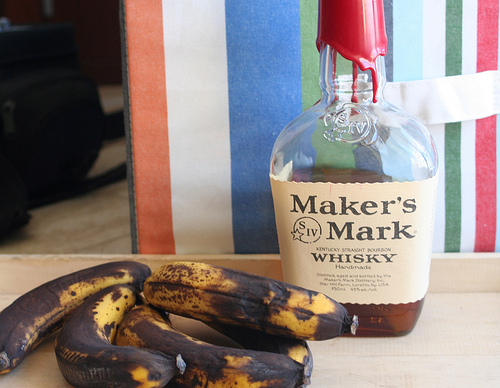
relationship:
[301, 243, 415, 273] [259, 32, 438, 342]
word on bottle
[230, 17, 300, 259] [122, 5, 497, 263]
stripe on wall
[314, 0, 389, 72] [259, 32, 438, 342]
top on bottle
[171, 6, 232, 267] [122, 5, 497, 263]
stripe on wall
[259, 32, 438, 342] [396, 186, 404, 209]
bottle has apostrophe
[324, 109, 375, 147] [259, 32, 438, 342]
circle on bottle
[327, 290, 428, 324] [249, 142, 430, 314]
liquid in glass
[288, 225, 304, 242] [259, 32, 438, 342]
star on bottle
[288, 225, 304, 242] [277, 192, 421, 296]
star on label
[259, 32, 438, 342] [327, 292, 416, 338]
bottle has whisky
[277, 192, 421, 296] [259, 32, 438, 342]
label on bottle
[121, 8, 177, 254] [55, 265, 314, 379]
stripe behind bananas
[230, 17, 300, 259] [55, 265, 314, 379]
stripe behind bananas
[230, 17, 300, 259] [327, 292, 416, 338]
stripe behind whisky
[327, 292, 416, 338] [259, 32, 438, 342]
whisky in bottle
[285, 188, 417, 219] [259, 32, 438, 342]
maker's on bottle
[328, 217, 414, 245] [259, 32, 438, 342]
mark on bottle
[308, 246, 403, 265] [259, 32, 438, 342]
whisky on bottle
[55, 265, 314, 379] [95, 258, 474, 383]
bananas on table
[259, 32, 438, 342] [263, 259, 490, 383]
bottle on counter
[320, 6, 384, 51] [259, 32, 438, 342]
top on bottle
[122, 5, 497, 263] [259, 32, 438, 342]
wall behind bottle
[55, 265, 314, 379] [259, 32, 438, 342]
bananas near bottle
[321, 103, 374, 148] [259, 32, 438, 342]
circle on bottle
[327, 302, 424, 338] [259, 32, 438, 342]
liquid in bottle